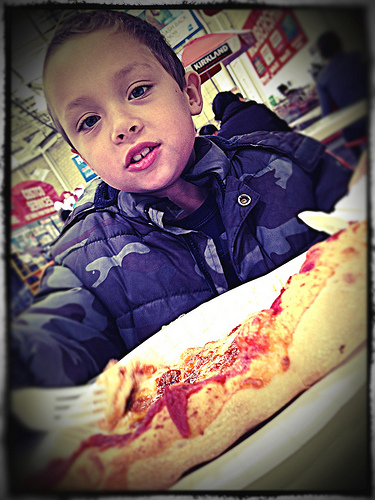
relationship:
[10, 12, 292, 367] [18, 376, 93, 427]
boy holding fork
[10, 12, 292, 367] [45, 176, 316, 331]
boy wearing jacket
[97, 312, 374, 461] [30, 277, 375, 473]
pizza on plate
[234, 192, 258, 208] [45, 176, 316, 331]
button on jacket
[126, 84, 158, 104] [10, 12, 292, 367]
eye on boy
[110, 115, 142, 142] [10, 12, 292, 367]
nose on boy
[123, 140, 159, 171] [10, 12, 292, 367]
mouth on boy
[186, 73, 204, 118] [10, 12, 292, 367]
ear on boy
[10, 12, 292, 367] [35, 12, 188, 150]
boy with hair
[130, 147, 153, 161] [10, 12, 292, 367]
teeth on boy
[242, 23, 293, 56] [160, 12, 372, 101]
advertisement on wall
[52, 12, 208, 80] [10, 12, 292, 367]
hair on boy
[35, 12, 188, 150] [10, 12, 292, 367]
hair on boy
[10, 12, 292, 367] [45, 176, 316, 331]
boy wearing a jacket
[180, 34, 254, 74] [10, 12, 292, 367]
umbrella behind boy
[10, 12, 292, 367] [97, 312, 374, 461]
boy eating pizza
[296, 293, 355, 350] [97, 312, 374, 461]
crust on pizza